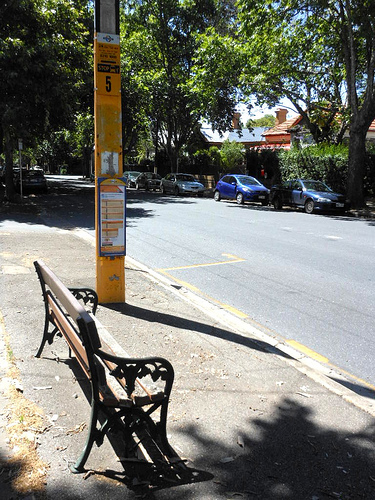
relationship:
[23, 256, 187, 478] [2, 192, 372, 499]
bench on top of sidewalk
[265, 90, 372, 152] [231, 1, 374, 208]
house behind tree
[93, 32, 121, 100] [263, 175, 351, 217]
sign behind car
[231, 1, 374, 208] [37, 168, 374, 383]
tree near road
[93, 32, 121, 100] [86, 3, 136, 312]
sign on top of pole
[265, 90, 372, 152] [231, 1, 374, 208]
house near tree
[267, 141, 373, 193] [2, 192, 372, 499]
bush near sidewalk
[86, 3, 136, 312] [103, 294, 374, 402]
pole has shadow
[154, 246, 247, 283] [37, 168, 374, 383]
line in road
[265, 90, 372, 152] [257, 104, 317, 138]
house has roof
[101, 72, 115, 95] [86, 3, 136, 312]
number on pole